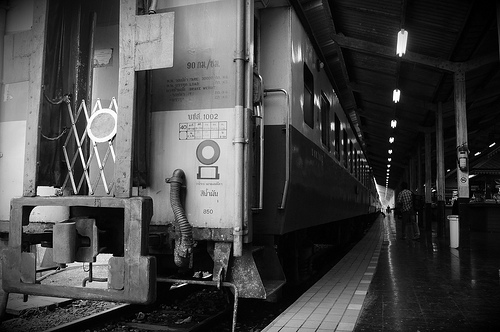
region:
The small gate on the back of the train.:
[57, 97, 114, 196]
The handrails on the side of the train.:
[257, 76, 288, 221]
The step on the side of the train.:
[240, 241, 289, 296]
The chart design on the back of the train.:
[178, 120, 229, 140]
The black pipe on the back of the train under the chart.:
[162, 172, 196, 269]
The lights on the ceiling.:
[379, 27, 411, 207]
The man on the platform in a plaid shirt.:
[394, 182, 413, 250]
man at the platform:
[386, 178, 425, 237]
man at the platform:
[389, 178, 422, 232]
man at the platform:
[389, 165, 417, 240]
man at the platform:
[383, 172, 422, 239]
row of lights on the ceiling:
[365, 8, 413, 231]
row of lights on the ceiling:
[366, 16, 416, 202]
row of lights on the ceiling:
[360, 19, 414, 245]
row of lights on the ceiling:
[360, 26, 416, 231]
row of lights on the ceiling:
[360, 13, 408, 202]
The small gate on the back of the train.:
[57, 92, 121, 197]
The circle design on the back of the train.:
[195, 140, 220, 165]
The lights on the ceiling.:
[380, 89, 398, 205]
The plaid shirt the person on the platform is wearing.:
[399, 188, 413, 208]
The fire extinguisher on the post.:
[457, 136, 468, 174]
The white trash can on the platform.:
[451, 214, 461, 248]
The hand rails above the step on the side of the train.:
[252, 72, 290, 216]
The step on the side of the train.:
[242, 245, 292, 300]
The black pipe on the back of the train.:
[167, 168, 205, 269]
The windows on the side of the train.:
[303, 75, 384, 195]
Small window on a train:
[290, 56, 312, 142]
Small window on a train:
[318, 81, 329, 171]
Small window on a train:
[331, 106, 342, 171]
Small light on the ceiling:
[390, 14, 416, 67]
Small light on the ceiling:
[383, 84, 408, 105]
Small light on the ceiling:
[385, 117, 406, 134]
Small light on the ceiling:
[382, 131, 399, 152]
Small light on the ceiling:
[383, 149, 395, 159]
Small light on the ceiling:
[381, 177, 391, 187]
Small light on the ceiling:
[380, 166, 395, 177]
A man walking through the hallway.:
[386, 175, 428, 243]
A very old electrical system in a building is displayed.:
[145, 103, 258, 245]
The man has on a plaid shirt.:
[396, 183, 417, 213]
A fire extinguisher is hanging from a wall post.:
[459, 140, 470, 170]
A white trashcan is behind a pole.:
[442, 212, 469, 249]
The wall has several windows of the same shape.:
[301, 62, 333, 147]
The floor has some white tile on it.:
[305, 250, 372, 312]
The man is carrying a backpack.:
[413, 192, 428, 214]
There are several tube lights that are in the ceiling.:
[389, 20, 412, 109]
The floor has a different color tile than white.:
[388, 258, 487, 329]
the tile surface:
[260, 202, 378, 329]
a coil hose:
[166, 169, 195, 254]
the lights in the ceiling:
[381, 15, 411, 192]